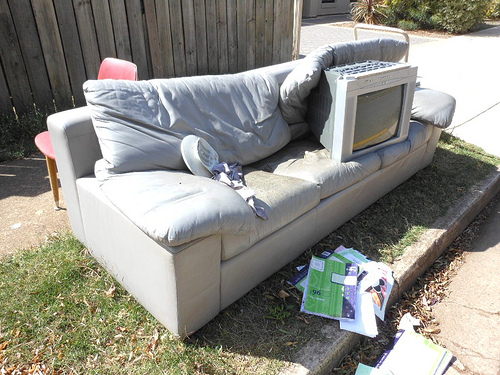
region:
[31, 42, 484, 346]
White couch lying on street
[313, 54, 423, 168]
Old television on white couch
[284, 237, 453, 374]
Papers lying next to white couch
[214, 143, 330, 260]
Cushion is dirty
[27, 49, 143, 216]
read chair behind couch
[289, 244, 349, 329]
Green paper next to couch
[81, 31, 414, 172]
Two pillows on couch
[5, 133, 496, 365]
Couch sitting on grass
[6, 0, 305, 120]
Wood fence in the background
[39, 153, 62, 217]
Red chair with wood legs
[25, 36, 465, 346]
A SOFA OUT ON THE CURB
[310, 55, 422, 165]
COMPUTER SCREEN ON THE SOFA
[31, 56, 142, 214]
A RED CHAIR BEHIND THE SOFA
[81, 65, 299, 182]
LARGE WHITE SOFA CUSHION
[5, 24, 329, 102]
A WOODEN FENCE BEHIND THE SOFA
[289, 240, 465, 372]
A BUNCH OF PAPER ON THE CURB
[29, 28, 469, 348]
A SOFA SITTING ON THE GRASS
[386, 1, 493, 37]
A BUSH IN THE BACKGROUND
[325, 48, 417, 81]
A KEYBOARD ON TOP OF THE MONITOR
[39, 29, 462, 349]
A SOFA OUT IN THE SUN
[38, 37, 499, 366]
A couch out on the sidewalk.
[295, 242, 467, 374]
Discarded pieces of mail.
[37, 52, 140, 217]
A red chair behind the couch.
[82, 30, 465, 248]
Pillows on the couch.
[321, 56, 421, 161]
An television on top of the couch.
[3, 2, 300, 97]
Wooden fence in the background.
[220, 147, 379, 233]
Two dirty seat cushions.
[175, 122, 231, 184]
A small white dish.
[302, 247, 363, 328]
The paper is green, white and blue.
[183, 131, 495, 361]
Shadows created by the couch and television.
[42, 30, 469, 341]
gray couch sitting on the curb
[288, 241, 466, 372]
pile of papers and magazines on the ground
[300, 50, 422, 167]
old television sitting on the couch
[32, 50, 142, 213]
red chair behind the couch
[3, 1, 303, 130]
a wooden fence in the background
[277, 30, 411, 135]
a smushed couch cushion on top of the TV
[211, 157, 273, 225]
a piece of crumpled up clothing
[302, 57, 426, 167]
an old computer monitor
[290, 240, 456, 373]
a stack of junk mail next to the curb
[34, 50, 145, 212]
a red chair on the sidewalk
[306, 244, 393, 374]
Papers sitting on grass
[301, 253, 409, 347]
Green and white papers on the ground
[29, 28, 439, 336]
Gray couch sitting on grass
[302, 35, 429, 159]
Tv on a couch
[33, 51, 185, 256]
Red chair behind a couch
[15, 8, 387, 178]
Gray fence behind a couch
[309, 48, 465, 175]
Silver TV outside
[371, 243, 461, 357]
Leaves on the gray street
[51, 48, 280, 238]
Fluffy gray couch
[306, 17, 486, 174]
Driveway next to a couch